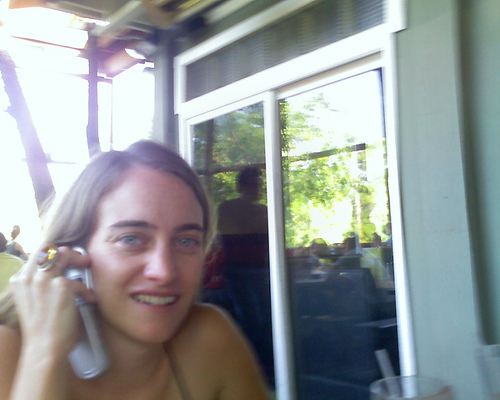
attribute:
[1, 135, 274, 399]
woman — young, smiling, looking, blonde, chatting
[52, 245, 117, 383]
phone — portable, white, silver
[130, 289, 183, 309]
teeth — white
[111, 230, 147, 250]
eye — blue, light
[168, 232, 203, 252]
eye — blue, light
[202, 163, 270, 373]
reflection — man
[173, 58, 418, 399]
door — glass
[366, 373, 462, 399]
drink — clear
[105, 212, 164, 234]
eyebrow — brown, dark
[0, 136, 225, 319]
hair — light brown, back-lit, grey, light, blonde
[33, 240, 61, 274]
ring — amber, large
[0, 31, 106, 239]
woods — brown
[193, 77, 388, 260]
trees — green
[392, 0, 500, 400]
wall — grey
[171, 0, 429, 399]
frame — white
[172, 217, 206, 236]
eyebrow — dark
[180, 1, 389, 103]
vent — rectangular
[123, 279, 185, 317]
smile — open mouthed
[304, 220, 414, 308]
people — eating